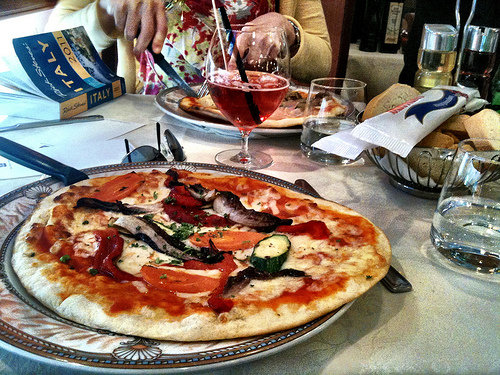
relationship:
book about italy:
[8, 22, 143, 119] [40, 38, 81, 103]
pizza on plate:
[42, 143, 360, 358] [13, 286, 86, 352]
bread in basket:
[370, 74, 498, 147] [387, 85, 494, 201]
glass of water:
[259, 53, 375, 166] [312, 74, 371, 182]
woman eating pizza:
[93, 1, 347, 109] [42, 143, 360, 358]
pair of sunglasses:
[100, 95, 205, 173] [112, 125, 251, 216]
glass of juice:
[259, 53, 375, 166] [176, 51, 322, 138]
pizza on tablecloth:
[42, 143, 360, 358] [116, 87, 182, 192]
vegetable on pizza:
[79, 233, 290, 305] [42, 143, 360, 358]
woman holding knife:
[93, 1, 347, 109] [131, 27, 196, 100]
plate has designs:
[13, 286, 86, 352] [5, 187, 30, 235]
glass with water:
[259, 53, 375, 166] [312, 74, 371, 182]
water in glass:
[312, 74, 371, 182] [259, 53, 375, 166]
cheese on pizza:
[63, 187, 308, 333] [42, 143, 360, 358]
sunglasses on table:
[112, 125, 251, 216] [44, 110, 226, 190]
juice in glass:
[204, 74, 287, 131] [259, 53, 375, 166]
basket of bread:
[387, 85, 494, 201] [370, 74, 498, 147]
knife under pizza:
[131, 27, 196, 100] [42, 143, 360, 358]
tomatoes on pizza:
[147, 153, 330, 262] [42, 143, 360, 358]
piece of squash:
[218, 225, 295, 271] [222, 197, 291, 315]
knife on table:
[131, 27, 196, 100] [44, 110, 226, 190]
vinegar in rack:
[450, 5, 495, 122] [417, 13, 495, 76]